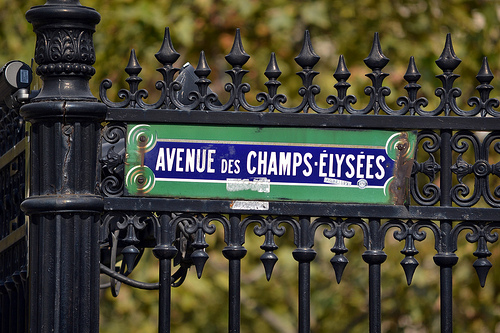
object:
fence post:
[18, 0, 108, 333]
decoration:
[33, 25, 95, 79]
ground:
[331, 114, 368, 194]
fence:
[22, 3, 500, 332]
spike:
[434, 33, 464, 89]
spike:
[403, 55, 424, 99]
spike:
[361, 27, 392, 87]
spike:
[330, 54, 352, 98]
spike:
[262, 50, 283, 98]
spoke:
[435, 31, 457, 331]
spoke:
[363, 28, 397, 330]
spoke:
[294, 27, 316, 332]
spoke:
[224, 27, 251, 332]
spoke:
[153, 26, 180, 331]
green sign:
[124, 124, 419, 206]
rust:
[393, 131, 414, 206]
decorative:
[116, 48, 148, 108]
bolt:
[139, 135, 146, 142]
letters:
[154, 146, 387, 180]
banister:
[219, 217, 247, 332]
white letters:
[155, 148, 166, 172]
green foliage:
[421, 1, 498, 20]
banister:
[291, 215, 317, 332]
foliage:
[105, 0, 166, 42]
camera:
[101, 125, 125, 161]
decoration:
[152, 26, 184, 110]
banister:
[150, 207, 180, 332]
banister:
[361, 213, 388, 333]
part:
[254, 52, 288, 112]